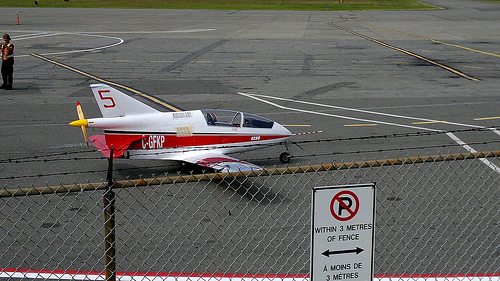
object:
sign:
[308, 183, 375, 281]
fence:
[0, 125, 499, 281]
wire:
[288, 139, 498, 158]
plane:
[71, 80, 296, 182]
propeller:
[76, 100, 84, 120]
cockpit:
[200, 110, 241, 128]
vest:
[0, 42, 15, 59]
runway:
[1, 5, 500, 279]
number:
[97, 89, 118, 108]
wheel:
[279, 152, 291, 163]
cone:
[15, 11, 21, 24]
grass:
[0, 0, 447, 10]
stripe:
[343, 124, 377, 126]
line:
[34, 55, 183, 111]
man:
[0, 34, 16, 91]